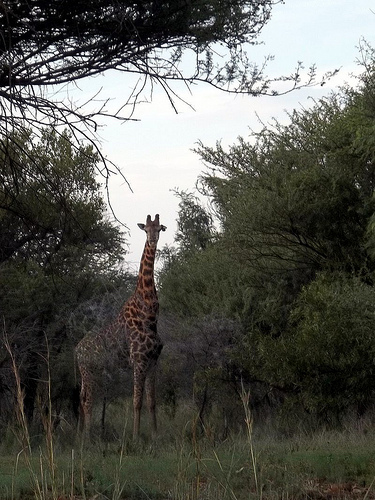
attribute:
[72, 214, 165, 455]
giraffe — large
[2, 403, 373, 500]
field — yellow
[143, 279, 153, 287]
spot — brown, orange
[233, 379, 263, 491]
plant blade — tall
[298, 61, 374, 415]
tree — tall, leafy, old, dark green, green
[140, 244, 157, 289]
neck — long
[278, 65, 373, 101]
cloud — white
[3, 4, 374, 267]
sky — light blue, cloudy, blue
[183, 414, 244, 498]
grass — tall, yellowed, green, wild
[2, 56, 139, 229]
branch — bare, brown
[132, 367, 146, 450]
leg — long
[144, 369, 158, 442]
leg — long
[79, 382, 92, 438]
leg — long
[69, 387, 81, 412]
hair — black